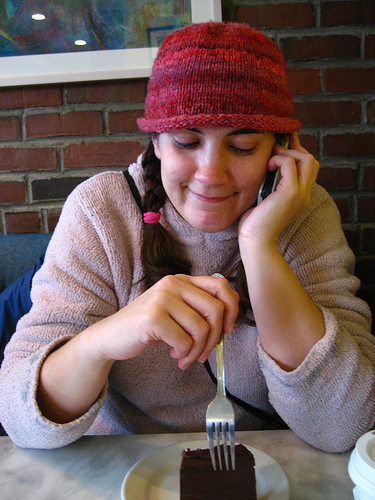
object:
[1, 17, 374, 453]
woman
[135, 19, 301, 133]
hat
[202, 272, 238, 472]
fork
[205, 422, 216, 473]
tines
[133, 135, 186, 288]
braid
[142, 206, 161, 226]
elastic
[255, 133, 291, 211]
cellphone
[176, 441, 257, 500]
cake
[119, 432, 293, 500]
plate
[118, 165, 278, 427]
strap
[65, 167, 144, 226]
shoulder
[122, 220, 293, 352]
chest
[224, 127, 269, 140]
eyebrows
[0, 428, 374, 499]
table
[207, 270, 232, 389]
handle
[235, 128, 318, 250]
hand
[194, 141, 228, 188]
nose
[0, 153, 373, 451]
sweater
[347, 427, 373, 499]
plates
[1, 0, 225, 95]
picture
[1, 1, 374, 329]
wall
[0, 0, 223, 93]
frame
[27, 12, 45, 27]
light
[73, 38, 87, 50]
light